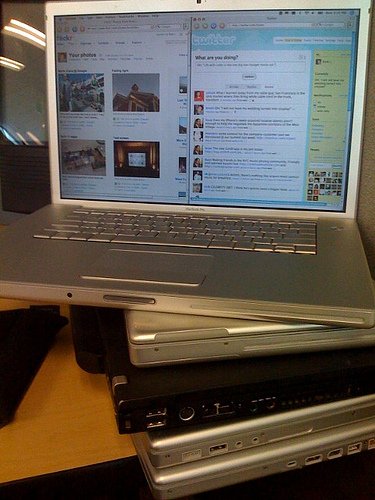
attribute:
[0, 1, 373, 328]
silver laptop — open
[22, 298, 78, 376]
cord — port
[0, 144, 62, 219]
wall — brick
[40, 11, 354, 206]
website — flikr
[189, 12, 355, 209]
website — google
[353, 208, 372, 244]
cord — port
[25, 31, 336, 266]
laptop — silver 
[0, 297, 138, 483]
desk — light, wooden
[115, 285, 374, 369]
laptop — stack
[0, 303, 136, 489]
table — wooden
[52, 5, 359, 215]
window — open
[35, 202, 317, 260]
keyboard — silver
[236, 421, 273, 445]
holes — headphone holes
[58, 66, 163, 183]
photos — large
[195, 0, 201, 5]
camera lens — black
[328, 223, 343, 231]
button — on/off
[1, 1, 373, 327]
laptop — silver, opened, pile, open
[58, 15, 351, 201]
screen — on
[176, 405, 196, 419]
hole — round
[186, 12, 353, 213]
twittter page — open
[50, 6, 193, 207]
flikr page — open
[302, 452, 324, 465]
slot — digitial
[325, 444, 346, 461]
slot — input